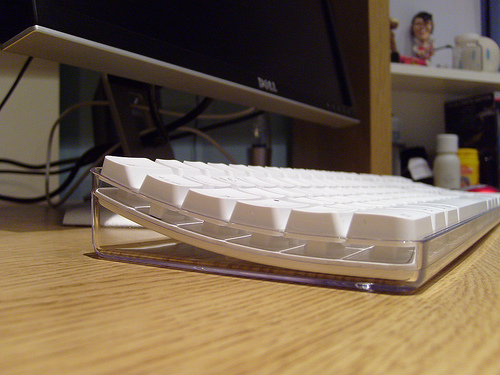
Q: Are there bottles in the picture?
A: Yes, there is a bottle.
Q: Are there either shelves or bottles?
A: Yes, there is a bottle.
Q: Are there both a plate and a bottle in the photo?
A: No, there is a bottle but no plates.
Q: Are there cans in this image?
A: No, there are no cans.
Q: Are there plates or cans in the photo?
A: No, there are no cans or plates.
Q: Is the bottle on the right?
A: Yes, the bottle is on the right of the image.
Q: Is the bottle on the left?
A: No, the bottle is on the right of the image.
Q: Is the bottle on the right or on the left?
A: The bottle is on the right of the image.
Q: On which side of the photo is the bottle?
A: The bottle is on the right of the image.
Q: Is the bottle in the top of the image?
A: Yes, the bottle is in the top of the image.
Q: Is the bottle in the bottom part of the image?
A: No, the bottle is in the top of the image.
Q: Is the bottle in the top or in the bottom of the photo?
A: The bottle is in the top of the image.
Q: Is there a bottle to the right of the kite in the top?
A: Yes, there is a bottle to the right of the kite.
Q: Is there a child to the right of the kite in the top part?
A: No, there is a bottle to the right of the kite.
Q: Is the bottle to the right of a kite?
A: Yes, the bottle is to the right of a kite.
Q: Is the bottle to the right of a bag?
A: No, the bottle is to the right of a kite.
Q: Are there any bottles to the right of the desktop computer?
A: Yes, there is a bottle to the right of the desktop computer.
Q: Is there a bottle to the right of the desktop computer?
A: Yes, there is a bottle to the right of the desktop computer.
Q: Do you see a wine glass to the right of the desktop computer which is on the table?
A: No, there is a bottle to the right of the desktop computer.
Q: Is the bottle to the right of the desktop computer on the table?
A: Yes, the bottle is to the right of the desktop computer.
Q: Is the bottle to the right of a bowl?
A: No, the bottle is to the right of the desktop computer.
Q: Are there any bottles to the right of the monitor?
A: Yes, there is a bottle to the right of the monitor.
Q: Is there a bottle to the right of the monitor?
A: Yes, there is a bottle to the right of the monitor.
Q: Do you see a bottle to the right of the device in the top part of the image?
A: Yes, there is a bottle to the right of the monitor.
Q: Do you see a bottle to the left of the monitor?
A: No, the bottle is to the right of the monitor.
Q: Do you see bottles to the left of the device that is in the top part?
A: No, the bottle is to the right of the monitor.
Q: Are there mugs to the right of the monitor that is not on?
A: No, there is a bottle to the right of the monitor.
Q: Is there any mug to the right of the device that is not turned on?
A: No, there is a bottle to the right of the monitor.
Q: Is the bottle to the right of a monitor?
A: Yes, the bottle is to the right of a monitor.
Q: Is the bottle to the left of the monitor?
A: No, the bottle is to the right of the monitor.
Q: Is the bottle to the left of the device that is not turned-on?
A: No, the bottle is to the right of the monitor.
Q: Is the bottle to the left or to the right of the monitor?
A: The bottle is to the right of the monitor.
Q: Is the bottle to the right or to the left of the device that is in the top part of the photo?
A: The bottle is to the right of the monitor.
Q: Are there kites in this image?
A: Yes, there is a kite.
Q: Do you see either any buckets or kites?
A: Yes, there is a kite.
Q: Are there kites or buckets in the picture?
A: Yes, there is a kite.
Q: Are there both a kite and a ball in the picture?
A: No, there is a kite but no balls.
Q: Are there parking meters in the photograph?
A: No, there are no parking meters.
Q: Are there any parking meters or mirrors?
A: No, there are no parking meters or mirrors.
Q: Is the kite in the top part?
A: Yes, the kite is in the top of the image.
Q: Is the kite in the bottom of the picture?
A: No, the kite is in the top of the image.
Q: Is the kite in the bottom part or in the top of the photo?
A: The kite is in the top of the image.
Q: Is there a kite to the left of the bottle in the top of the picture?
A: Yes, there is a kite to the left of the bottle.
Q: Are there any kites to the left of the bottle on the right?
A: Yes, there is a kite to the left of the bottle.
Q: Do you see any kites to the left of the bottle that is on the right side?
A: Yes, there is a kite to the left of the bottle.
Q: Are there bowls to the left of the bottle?
A: No, there is a kite to the left of the bottle.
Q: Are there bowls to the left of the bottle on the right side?
A: No, there is a kite to the left of the bottle.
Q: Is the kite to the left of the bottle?
A: Yes, the kite is to the left of the bottle.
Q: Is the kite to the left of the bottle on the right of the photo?
A: Yes, the kite is to the left of the bottle.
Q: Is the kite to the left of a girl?
A: No, the kite is to the left of the bottle.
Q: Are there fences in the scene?
A: No, there are no fences.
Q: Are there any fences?
A: No, there are no fences.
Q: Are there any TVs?
A: No, there are no tvs.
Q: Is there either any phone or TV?
A: No, there are no televisions or phones.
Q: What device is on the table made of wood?
A: The device is a desktop computer.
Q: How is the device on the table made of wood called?
A: The device is a desktop computer.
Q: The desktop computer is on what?
A: The desktop computer is on the table.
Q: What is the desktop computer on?
A: The desktop computer is on the table.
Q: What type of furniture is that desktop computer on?
A: The desktop computer is on the table.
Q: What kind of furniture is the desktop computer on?
A: The desktop computer is on the table.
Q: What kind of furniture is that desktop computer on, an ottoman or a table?
A: The desktop computer is on a table.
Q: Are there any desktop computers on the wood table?
A: Yes, there is a desktop computer on the table.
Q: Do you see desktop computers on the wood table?
A: Yes, there is a desktop computer on the table.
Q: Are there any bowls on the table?
A: No, there is a desktop computer on the table.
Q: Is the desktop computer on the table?
A: Yes, the desktop computer is on the table.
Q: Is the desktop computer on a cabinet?
A: No, the desktop computer is on the table.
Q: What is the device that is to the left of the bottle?
A: The device is a desktop computer.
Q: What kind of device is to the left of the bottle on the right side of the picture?
A: The device is a desktop computer.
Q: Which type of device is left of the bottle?
A: The device is a desktop computer.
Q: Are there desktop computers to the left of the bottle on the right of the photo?
A: Yes, there is a desktop computer to the left of the bottle.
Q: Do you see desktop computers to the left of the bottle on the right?
A: Yes, there is a desktop computer to the left of the bottle.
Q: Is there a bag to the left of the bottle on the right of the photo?
A: No, there is a desktop computer to the left of the bottle.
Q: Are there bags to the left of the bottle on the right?
A: No, there is a desktop computer to the left of the bottle.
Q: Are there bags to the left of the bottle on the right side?
A: No, there is a desktop computer to the left of the bottle.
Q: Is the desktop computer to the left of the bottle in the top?
A: Yes, the desktop computer is to the left of the bottle.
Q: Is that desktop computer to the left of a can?
A: No, the desktop computer is to the left of the bottle.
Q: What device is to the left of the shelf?
A: The device is a desktop computer.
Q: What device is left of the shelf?
A: The device is a desktop computer.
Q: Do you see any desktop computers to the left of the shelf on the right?
A: Yes, there is a desktop computer to the left of the shelf.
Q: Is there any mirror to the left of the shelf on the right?
A: No, there is a desktop computer to the left of the shelf.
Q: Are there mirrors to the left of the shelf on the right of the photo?
A: No, there is a desktop computer to the left of the shelf.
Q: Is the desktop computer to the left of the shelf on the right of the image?
A: Yes, the desktop computer is to the left of the shelf.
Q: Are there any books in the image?
A: No, there are no books.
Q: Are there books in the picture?
A: No, there are no books.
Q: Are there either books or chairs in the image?
A: No, there are no books or chairs.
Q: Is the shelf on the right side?
A: Yes, the shelf is on the right of the image.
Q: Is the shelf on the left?
A: No, the shelf is on the right of the image.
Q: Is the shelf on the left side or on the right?
A: The shelf is on the right of the image.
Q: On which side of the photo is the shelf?
A: The shelf is on the right of the image.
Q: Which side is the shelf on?
A: The shelf is on the right of the image.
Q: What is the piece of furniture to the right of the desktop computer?
A: The piece of furniture is a shelf.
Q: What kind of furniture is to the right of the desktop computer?
A: The piece of furniture is a shelf.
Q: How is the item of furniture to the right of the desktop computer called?
A: The piece of furniture is a shelf.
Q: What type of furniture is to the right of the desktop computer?
A: The piece of furniture is a shelf.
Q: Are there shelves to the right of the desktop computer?
A: Yes, there is a shelf to the right of the desktop computer.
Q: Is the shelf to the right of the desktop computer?
A: Yes, the shelf is to the right of the desktop computer.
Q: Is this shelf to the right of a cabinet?
A: No, the shelf is to the right of the desktop computer.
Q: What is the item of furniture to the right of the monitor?
A: The piece of furniture is a shelf.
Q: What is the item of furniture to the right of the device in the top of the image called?
A: The piece of furniture is a shelf.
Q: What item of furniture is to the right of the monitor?
A: The piece of furniture is a shelf.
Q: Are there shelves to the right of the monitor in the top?
A: Yes, there is a shelf to the right of the monitor.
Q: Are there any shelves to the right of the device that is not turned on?
A: Yes, there is a shelf to the right of the monitor.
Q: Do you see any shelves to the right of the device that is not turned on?
A: Yes, there is a shelf to the right of the monitor.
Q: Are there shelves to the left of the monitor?
A: No, the shelf is to the right of the monitor.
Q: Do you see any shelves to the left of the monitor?
A: No, the shelf is to the right of the monitor.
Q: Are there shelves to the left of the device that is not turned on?
A: No, the shelf is to the right of the monitor.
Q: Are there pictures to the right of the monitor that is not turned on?
A: No, there is a shelf to the right of the monitor.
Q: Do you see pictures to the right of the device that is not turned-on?
A: No, there is a shelf to the right of the monitor.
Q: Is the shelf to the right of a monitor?
A: Yes, the shelf is to the right of a monitor.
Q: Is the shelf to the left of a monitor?
A: No, the shelf is to the right of a monitor.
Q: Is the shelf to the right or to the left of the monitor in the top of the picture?
A: The shelf is to the right of the monitor.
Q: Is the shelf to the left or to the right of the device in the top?
A: The shelf is to the right of the monitor.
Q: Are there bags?
A: No, there are no bags.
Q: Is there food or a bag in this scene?
A: No, there are no bags or food.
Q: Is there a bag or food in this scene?
A: No, there are no bags or food.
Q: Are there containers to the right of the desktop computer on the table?
A: Yes, there are containers to the right of the desktop computer.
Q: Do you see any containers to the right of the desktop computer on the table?
A: Yes, there are containers to the right of the desktop computer.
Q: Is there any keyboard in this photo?
A: Yes, there is a keyboard.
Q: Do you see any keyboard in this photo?
A: Yes, there is a keyboard.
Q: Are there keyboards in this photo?
A: Yes, there is a keyboard.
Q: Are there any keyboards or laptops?
A: Yes, there is a keyboard.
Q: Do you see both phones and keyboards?
A: No, there is a keyboard but no phones.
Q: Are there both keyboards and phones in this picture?
A: No, there is a keyboard but no phones.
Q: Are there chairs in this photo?
A: No, there are no chairs.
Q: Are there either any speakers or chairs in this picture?
A: No, there are no chairs or speakers.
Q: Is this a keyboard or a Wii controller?
A: This is a keyboard.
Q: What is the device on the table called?
A: The device is a keyboard.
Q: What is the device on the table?
A: The device is a keyboard.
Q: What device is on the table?
A: The device is a keyboard.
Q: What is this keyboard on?
A: The keyboard is on the table.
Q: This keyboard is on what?
A: The keyboard is on the table.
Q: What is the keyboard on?
A: The keyboard is on the table.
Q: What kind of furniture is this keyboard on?
A: The keyboard is on the table.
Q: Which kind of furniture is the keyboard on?
A: The keyboard is on the table.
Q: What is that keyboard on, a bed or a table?
A: The keyboard is on a table.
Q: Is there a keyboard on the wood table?
A: Yes, there is a keyboard on the table.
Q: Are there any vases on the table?
A: No, there is a keyboard on the table.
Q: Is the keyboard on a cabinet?
A: No, the keyboard is on the table.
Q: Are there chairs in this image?
A: No, there are no chairs.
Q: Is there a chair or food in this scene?
A: No, there are no chairs or food.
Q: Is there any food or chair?
A: No, there are no chairs or food.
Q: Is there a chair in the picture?
A: No, there are no chairs.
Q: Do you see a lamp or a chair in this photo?
A: No, there are no chairs or lamps.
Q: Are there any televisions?
A: No, there are no televisions.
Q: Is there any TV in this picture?
A: No, there are no televisions.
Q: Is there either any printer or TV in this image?
A: No, there are no televisions or printers.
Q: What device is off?
A: The device is a monitor.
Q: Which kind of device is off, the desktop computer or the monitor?
A: The monitor is off.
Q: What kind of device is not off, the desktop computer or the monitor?
A: The desktop computer is not off.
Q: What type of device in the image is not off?
A: The device is a desktop computer.